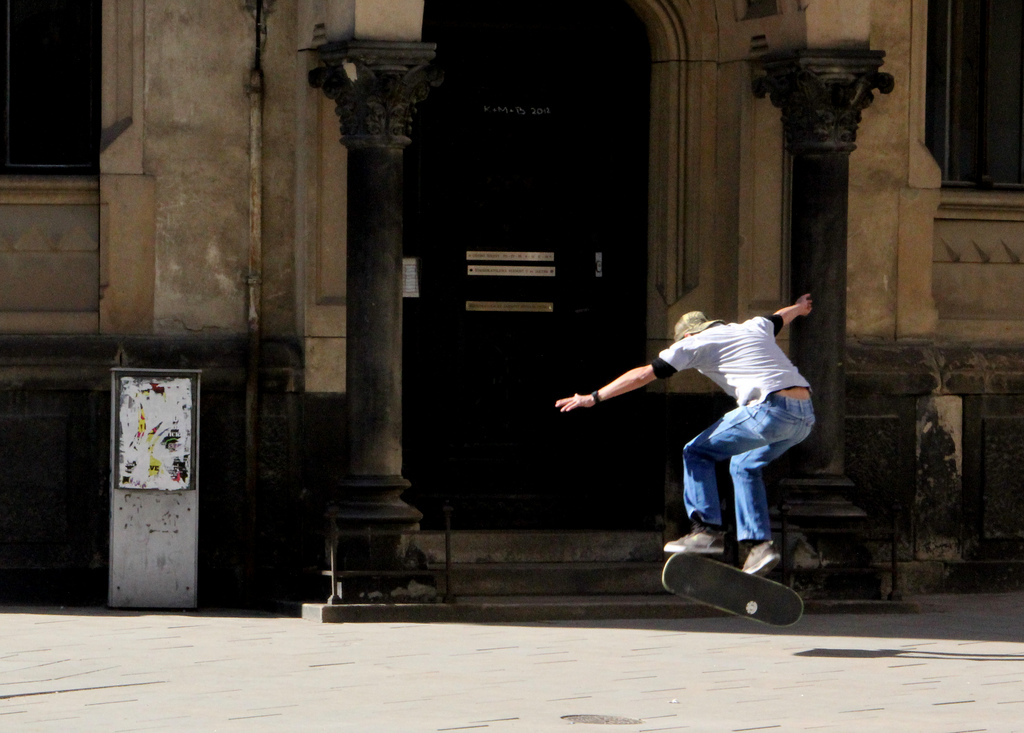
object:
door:
[402, 1, 649, 530]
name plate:
[466, 251, 554, 261]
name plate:
[466, 265, 554, 276]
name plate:
[466, 301, 553, 311]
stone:
[848, 101, 939, 594]